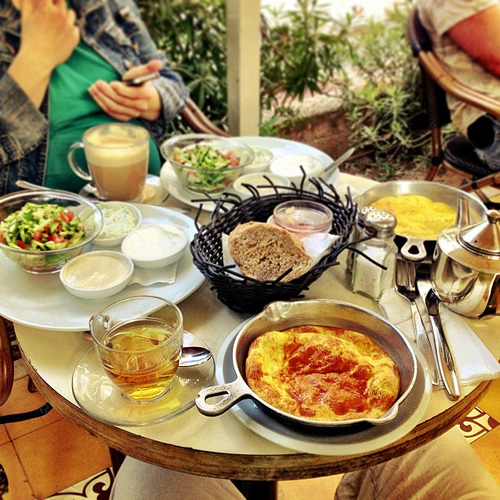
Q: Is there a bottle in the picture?
A: No, there are no bottles.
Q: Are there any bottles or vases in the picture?
A: No, there are no bottles or vases.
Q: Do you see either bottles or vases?
A: No, there are no bottles or vases.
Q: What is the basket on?
A: The basket is on the table.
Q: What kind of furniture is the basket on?
A: The basket is on the table.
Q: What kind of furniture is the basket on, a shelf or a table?
A: The basket is on a table.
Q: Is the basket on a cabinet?
A: No, the basket is on the table.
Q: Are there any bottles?
A: No, there are no bottles.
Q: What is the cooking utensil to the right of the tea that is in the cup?
A: The cooking utensil is a skillet.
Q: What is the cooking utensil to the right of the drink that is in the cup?
A: The cooking utensil is a skillet.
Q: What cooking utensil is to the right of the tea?
A: The cooking utensil is a skillet.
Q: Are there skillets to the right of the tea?
A: Yes, there is a skillet to the right of the tea.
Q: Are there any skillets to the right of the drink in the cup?
A: Yes, there is a skillet to the right of the tea.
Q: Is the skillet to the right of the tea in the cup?
A: Yes, the skillet is to the right of the tea.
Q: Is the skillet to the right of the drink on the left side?
A: Yes, the skillet is to the right of the tea.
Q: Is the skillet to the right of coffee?
A: No, the skillet is to the right of the tea.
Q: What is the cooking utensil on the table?
A: The cooking utensil is a skillet.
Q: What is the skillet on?
A: The skillet is on the table.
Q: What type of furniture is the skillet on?
A: The skillet is on the table.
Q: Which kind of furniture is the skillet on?
A: The skillet is on the table.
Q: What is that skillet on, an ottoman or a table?
A: The skillet is on a table.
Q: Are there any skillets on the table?
A: Yes, there is a skillet on the table.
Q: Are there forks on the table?
A: No, there is a skillet on the table.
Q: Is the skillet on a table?
A: Yes, the skillet is on a table.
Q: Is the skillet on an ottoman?
A: No, the skillet is on a table.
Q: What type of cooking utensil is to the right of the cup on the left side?
A: The cooking utensil is a skillet.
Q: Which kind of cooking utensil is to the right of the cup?
A: The cooking utensil is a skillet.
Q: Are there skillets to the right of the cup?
A: Yes, there is a skillet to the right of the cup.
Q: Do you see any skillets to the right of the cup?
A: Yes, there is a skillet to the right of the cup.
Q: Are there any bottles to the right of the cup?
A: No, there is a skillet to the right of the cup.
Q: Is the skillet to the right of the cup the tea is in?
A: Yes, the skillet is to the right of the cup.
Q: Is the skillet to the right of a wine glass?
A: No, the skillet is to the right of the cup.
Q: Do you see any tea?
A: Yes, there is tea.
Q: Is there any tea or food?
A: Yes, there is tea.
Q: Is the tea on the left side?
A: Yes, the tea is on the left of the image.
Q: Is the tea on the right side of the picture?
A: No, the tea is on the left of the image.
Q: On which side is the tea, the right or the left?
A: The tea is on the left of the image.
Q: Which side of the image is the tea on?
A: The tea is on the left of the image.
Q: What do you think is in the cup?
A: The tea is in the cup.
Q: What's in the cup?
A: The tea is in the cup.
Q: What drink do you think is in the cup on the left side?
A: The drink is tea.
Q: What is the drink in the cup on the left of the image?
A: The drink is tea.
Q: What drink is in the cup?
A: The drink is tea.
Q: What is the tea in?
A: The tea is in the cup.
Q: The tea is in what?
A: The tea is in the cup.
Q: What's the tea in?
A: The tea is in the cup.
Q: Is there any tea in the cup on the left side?
A: Yes, there is tea in the cup.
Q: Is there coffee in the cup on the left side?
A: No, there is tea in the cup.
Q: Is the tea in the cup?
A: Yes, the tea is in the cup.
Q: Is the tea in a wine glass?
A: No, the tea is in the cup.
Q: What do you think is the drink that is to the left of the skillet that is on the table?
A: The drink is tea.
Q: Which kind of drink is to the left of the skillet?
A: The drink is tea.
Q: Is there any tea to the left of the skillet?
A: Yes, there is tea to the left of the skillet.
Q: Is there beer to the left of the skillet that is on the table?
A: No, there is tea to the left of the skillet.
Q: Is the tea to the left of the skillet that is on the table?
A: Yes, the tea is to the left of the skillet.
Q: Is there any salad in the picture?
A: Yes, there is salad.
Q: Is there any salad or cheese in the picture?
A: Yes, there is salad.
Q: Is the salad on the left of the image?
A: Yes, the salad is on the left of the image.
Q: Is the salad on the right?
A: No, the salad is on the left of the image.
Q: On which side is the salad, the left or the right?
A: The salad is on the left of the image.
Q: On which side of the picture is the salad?
A: The salad is on the left of the image.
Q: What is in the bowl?
A: The salad is in the bowl.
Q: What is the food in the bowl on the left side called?
A: The food is salad.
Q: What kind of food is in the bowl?
A: The food is salad.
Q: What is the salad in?
A: The salad is in the bowl.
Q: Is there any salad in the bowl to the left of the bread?
A: Yes, there is salad in the bowl.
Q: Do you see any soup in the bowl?
A: No, there is salad in the bowl.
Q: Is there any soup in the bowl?
A: No, there is salad in the bowl.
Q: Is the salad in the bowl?
A: Yes, the salad is in the bowl.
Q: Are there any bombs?
A: No, there are no bombs.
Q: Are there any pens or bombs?
A: No, there are no bombs or pens.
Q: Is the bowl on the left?
A: Yes, the bowl is on the left of the image.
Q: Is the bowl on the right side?
A: No, the bowl is on the left of the image.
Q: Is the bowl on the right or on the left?
A: The bowl is on the left of the image.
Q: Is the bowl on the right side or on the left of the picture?
A: The bowl is on the left of the image.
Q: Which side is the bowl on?
A: The bowl is on the left of the image.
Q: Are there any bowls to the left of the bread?
A: Yes, there is a bowl to the left of the bread.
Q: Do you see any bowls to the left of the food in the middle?
A: Yes, there is a bowl to the left of the bread.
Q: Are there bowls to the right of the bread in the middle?
A: No, the bowl is to the left of the bread.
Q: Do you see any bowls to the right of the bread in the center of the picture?
A: No, the bowl is to the left of the bread.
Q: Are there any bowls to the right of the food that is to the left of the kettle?
A: No, the bowl is to the left of the bread.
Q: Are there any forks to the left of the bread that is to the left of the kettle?
A: No, there is a bowl to the left of the bread.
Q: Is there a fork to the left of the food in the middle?
A: No, there is a bowl to the left of the bread.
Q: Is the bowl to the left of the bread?
A: Yes, the bowl is to the left of the bread.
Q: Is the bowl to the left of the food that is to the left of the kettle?
A: Yes, the bowl is to the left of the bread.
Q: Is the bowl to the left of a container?
A: No, the bowl is to the left of the bread.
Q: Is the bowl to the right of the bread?
A: No, the bowl is to the left of the bread.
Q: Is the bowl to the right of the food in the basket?
A: No, the bowl is to the left of the bread.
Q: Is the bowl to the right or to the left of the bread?
A: The bowl is to the left of the bread.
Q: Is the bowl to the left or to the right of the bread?
A: The bowl is to the left of the bread.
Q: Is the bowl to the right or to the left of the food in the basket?
A: The bowl is to the left of the bread.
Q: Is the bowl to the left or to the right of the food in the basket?
A: The bowl is to the left of the bread.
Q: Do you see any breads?
A: Yes, there is a bread.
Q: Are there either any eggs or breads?
A: Yes, there is a bread.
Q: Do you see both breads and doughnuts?
A: No, there is a bread but no donuts.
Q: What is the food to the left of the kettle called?
A: The food is a bread.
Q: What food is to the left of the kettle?
A: The food is a bread.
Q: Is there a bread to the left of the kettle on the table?
A: Yes, there is a bread to the left of the kettle.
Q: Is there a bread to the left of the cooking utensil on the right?
A: Yes, there is a bread to the left of the kettle.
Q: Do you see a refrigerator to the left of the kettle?
A: No, there is a bread to the left of the kettle.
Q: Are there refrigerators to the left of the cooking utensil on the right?
A: No, there is a bread to the left of the kettle.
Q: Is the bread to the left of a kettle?
A: Yes, the bread is to the left of a kettle.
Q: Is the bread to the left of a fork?
A: No, the bread is to the left of a kettle.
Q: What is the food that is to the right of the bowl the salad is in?
A: The food is a bread.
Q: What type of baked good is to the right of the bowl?
A: The food is a bread.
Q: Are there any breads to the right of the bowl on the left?
A: Yes, there is a bread to the right of the bowl.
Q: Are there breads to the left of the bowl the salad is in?
A: No, the bread is to the right of the bowl.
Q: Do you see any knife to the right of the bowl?
A: No, there is a bread to the right of the bowl.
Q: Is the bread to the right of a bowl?
A: Yes, the bread is to the right of a bowl.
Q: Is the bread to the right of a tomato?
A: No, the bread is to the right of a bowl.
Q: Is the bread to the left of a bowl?
A: No, the bread is to the right of a bowl.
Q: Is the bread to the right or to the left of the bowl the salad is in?
A: The bread is to the right of the bowl.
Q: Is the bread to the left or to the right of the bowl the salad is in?
A: The bread is to the right of the bowl.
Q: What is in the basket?
A: The bread is in the basket.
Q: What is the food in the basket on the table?
A: The food is a bread.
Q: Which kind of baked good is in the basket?
A: The food is a bread.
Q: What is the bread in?
A: The bread is in the basket.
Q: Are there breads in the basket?
A: Yes, there is a bread in the basket.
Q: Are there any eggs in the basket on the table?
A: No, there is a bread in the basket.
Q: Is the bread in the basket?
A: Yes, the bread is in the basket.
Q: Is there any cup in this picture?
A: Yes, there is a cup.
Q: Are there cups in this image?
A: Yes, there is a cup.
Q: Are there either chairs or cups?
A: Yes, there is a cup.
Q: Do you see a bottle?
A: No, there are no bottles.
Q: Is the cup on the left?
A: Yes, the cup is on the left of the image.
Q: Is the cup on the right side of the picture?
A: No, the cup is on the left of the image.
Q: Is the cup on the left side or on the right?
A: The cup is on the left of the image.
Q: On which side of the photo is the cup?
A: The cup is on the left of the image.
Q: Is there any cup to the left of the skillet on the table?
A: Yes, there is a cup to the left of the skillet.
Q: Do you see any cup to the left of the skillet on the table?
A: Yes, there is a cup to the left of the skillet.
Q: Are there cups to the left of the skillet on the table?
A: Yes, there is a cup to the left of the skillet.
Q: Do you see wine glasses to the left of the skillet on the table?
A: No, there is a cup to the left of the skillet.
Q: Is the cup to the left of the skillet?
A: Yes, the cup is to the left of the skillet.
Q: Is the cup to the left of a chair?
A: No, the cup is to the left of the skillet.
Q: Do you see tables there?
A: Yes, there is a table.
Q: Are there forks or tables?
A: Yes, there is a table.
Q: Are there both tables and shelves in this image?
A: No, there is a table but no shelves.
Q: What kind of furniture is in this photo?
A: The furniture is a table.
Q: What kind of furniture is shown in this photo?
A: The furniture is a table.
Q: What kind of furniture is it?
A: The piece of furniture is a table.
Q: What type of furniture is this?
A: This is a table.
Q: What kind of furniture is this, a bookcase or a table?
A: This is a table.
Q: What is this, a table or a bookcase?
A: This is a table.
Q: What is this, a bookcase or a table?
A: This is a table.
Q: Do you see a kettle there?
A: Yes, there is a kettle.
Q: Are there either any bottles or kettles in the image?
A: Yes, there is a kettle.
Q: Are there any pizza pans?
A: No, there are no pizza pans.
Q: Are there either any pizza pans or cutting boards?
A: No, there are no pizza pans or cutting boards.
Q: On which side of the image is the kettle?
A: The kettle is on the right of the image.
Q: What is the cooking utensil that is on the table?
A: The cooking utensil is a kettle.